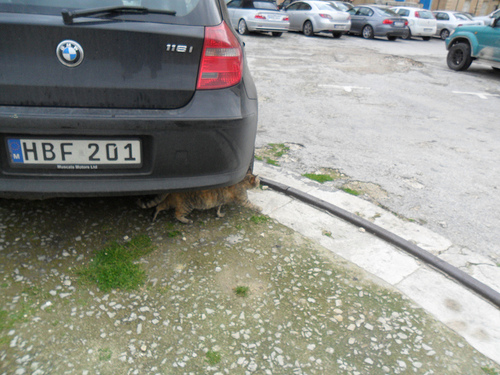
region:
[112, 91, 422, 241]
cat walking under car to street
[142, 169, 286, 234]
gold and brown striped cat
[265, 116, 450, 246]
street and curb in bad repair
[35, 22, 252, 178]
back end of black car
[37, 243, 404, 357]
patchy grass and gravel parking area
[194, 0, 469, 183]
quiet street or parking lot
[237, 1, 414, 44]
three cars silver and grey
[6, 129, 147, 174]
white license plate with black writing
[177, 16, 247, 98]
rear tail light on car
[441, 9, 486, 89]
front right of turquoise car looks old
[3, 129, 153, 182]
a license plate on the back on a black car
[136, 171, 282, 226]
a dirty orange stray tiger car under the car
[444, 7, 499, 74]
a blue-green vehicle in the parking lot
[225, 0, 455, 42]
a line of several cars parked in the parking lot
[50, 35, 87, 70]
the round BMW logo on the back of the car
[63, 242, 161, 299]
a green weed growing on the ground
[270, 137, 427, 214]
pot holes in the paved road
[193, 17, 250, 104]
the rear red brake light on the car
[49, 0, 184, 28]
the rear wind shield wiper on the car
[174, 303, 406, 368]
a very rocky dirt area next to the parking lot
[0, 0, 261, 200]
a gray BMW vehicle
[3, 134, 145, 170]
blue and black tag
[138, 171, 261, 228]
yellow and gray cat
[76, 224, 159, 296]
a spot of green grass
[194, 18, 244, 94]
red and white tail light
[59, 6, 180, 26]
a rear windshield wiper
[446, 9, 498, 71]
blue and white vehicle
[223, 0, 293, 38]
black and gray vehicle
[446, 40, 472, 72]
round black vehicle tire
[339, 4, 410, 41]
a small gray car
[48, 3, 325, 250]
calico cat under BMW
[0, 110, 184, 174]
someones license plate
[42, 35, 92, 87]
bmw symbol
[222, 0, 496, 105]
cars in a parking lot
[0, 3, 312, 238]
black bmw with a cat under it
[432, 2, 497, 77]
front of a blue truck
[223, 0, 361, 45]
two silver cars parked next to each other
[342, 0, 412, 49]
gray parked car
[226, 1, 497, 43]
row of parked cars in lot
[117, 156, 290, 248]
cat walking outside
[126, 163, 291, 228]
cat narrowly escapes certain death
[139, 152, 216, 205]
cat narrowly escapes certain death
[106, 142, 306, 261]
cat narrowly escapes certain death